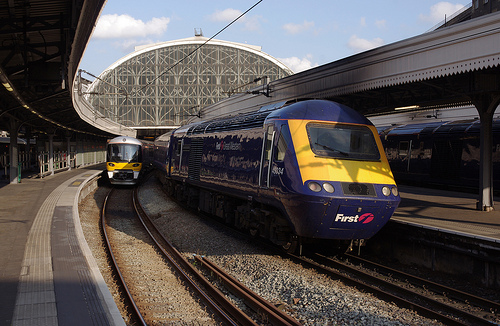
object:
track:
[97, 183, 269, 326]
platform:
[0, 159, 148, 326]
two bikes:
[96, 99, 401, 255]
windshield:
[301, 118, 383, 165]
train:
[93, 132, 154, 184]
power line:
[133, 0, 265, 94]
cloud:
[89, 10, 173, 39]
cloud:
[207, 4, 245, 23]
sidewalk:
[0, 170, 124, 326]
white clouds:
[276, 54, 318, 75]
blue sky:
[72, 0, 470, 79]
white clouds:
[345, 35, 386, 53]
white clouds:
[419, 2, 465, 20]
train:
[153, 97, 402, 256]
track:
[297, 245, 499, 326]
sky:
[67, 0, 480, 88]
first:
[333, 212, 360, 224]